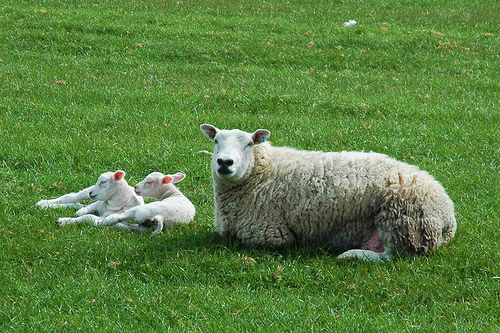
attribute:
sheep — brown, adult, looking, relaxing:
[199, 123, 458, 259]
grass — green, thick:
[2, 1, 500, 332]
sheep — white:
[97, 171, 197, 236]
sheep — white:
[36, 169, 145, 225]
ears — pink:
[162, 172, 188, 185]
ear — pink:
[113, 170, 128, 183]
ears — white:
[200, 123, 271, 147]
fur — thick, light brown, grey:
[214, 145, 458, 249]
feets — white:
[36, 197, 121, 225]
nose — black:
[216, 159, 237, 167]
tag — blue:
[259, 135, 267, 143]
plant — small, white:
[344, 17, 359, 29]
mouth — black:
[216, 168, 235, 176]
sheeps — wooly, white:
[36, 169, 198, 234]